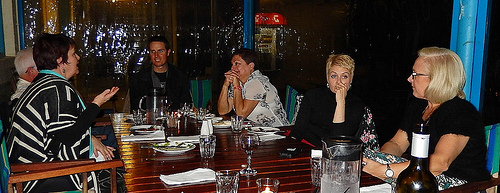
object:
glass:
[214, 170, 240, 191]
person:
[9, 34, 119, 191]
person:
[365, 44, 481, 177]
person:
[296, 52, 366, 152]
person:
[217, 47, 289, 124]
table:
[110, 102, 389, 191]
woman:
[368, 43, 488, 188]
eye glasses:
[411, 72, 431, 76]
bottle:
[400, 125, 437, 192]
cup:
[255, 177, 278, 192]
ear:
[324, 73, 330, 84]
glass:
[198, 121, 216, 160]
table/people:
[0, 29, 500, 193]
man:
[128, 36, 188, 116]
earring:
[54, 56, 61, 66]